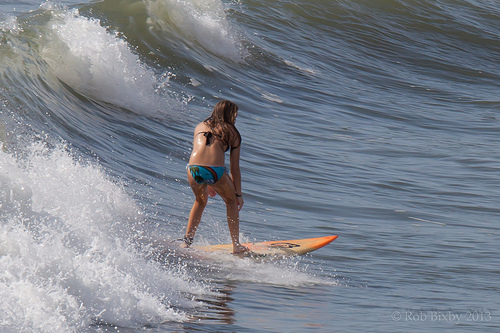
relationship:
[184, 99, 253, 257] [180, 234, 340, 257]
woman on surfboard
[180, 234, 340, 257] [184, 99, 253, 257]
surfboard under woman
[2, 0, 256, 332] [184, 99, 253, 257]
wave behind woman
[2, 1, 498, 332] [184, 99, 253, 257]
water ahead of woman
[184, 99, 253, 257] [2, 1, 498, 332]
woman in water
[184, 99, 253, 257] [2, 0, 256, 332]
woman riding wave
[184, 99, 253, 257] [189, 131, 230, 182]
woman wearing bikini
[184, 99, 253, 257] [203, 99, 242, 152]
woman has hair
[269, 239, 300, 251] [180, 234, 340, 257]
design on surfboard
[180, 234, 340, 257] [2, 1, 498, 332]
surfboard in water